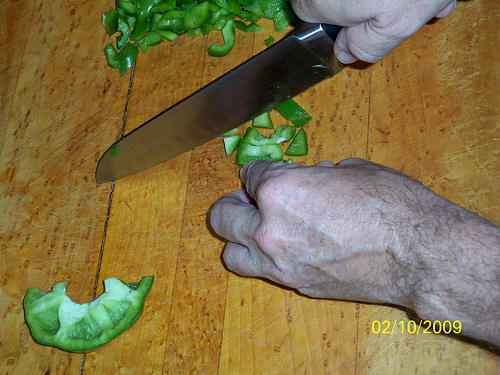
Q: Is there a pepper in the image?
A: Yes, there is a pepper.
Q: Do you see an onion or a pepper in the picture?
A: Yes, there is a pepper.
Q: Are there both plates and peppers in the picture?
A: No, there is a pepper but no plates.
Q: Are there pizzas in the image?
A: No, there are no pizzas.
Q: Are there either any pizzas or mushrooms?
A: No, there are no pizzas or mushrooms.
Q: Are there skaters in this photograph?
A: No, there are no skaters.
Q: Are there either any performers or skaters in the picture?
A: No, there are no skaters or performers.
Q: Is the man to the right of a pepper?
A: Yes, the man is to the right of a pepper.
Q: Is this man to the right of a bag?
A: No, the man is to the right of a pepper.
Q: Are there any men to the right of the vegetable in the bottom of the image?
A: Yes, there is a man to the right of the vegetable.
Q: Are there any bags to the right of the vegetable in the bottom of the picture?
A: No, there is a man to the right of the vegetable.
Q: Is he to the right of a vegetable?
A: Yes, the man is to the right of a vegetable.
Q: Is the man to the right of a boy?
A: No, the man is to the right of a vegetable.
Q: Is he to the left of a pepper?
A: No, the man is to the right of a pepper.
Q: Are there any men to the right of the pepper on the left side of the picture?
A: Yes, there is a man to the right of the pepper.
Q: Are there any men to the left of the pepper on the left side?
A: No, the man is to the right of the pepper.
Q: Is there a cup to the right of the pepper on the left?
A: No, there is a man to the right of the pepper.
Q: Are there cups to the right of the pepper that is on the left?
A: No, there is a man to the right of the pepper.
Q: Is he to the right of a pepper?
A: Yes, the man is to the right of a pepper.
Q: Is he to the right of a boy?
A: No, the man is to the right of a pepper.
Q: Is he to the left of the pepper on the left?
A: No, the man is to the right of the pepper.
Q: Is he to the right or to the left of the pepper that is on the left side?
A: The man is to the right of the pepper.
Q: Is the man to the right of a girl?
A: No, the man is to the right of a pepper.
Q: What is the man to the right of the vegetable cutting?
A: The man is cutting the pepper.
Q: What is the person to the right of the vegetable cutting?
A: The man is cutting the pepper.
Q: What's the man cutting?
A: The man is cutting the pepper.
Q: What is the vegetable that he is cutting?
A: The vegetable is a pepper.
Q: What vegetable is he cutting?
A: The man is cutting the pepper.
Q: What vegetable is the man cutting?
A: The man is cutting the pepper.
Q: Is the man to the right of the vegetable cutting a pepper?
A: Yes, the man is cutting a pepper.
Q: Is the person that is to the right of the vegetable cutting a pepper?
A: Yes, the man is cutting a pepper.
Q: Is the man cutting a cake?
A: No, the man is cutting a pepper.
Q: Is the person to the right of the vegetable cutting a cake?
A: No, the man is cutting a pepper.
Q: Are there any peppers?
A: Yes, there is a pepper.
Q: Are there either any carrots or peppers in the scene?
A: Yes, there is a pepper.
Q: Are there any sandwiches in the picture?
A: No, there are no sandwiches.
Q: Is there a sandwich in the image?
A: No, there are no sandwiches.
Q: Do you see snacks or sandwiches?
A: No, there are no sandwiches or snacks.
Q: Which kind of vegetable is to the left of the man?
A: The vegetable is a pepper.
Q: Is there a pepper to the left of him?
A: Yes, there is a pepper to the left of the man.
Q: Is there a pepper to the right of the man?
A: No, the pepper is to the left of the man.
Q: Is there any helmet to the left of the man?
A: No, there is a pepper to the left of the man.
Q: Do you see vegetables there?
A: Yes, there are vegetables.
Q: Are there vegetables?
A: Yes, there are vegetables.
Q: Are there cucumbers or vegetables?
A: Yes, there are vegetables.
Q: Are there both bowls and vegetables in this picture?
A: No, there are vegetables but no bowls.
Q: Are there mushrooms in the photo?
A: No, there are no mushrooms.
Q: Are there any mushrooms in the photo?
A: No, there are no mushrooms.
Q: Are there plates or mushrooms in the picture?
A: No, there are no mushrooms or plates.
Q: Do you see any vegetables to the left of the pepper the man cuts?
A: Yes, there are vegetables to the left of the pepper.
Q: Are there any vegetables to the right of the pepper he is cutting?
A: No, the vegetables are to the left of the pepper.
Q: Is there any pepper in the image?
A: Yes, there is a pepper.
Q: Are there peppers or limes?
A: Yes, there is a pepper.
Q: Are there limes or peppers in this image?
A: Yes, there is a pepper.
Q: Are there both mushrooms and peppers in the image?
A: No, there is a pepper but no mushrooms.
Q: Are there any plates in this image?
A: No, there are no plates.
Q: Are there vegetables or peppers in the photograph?
A: Yes, there is a pepper.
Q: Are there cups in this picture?
A: No, there are no cups.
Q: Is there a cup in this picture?
A: No, there are no cups.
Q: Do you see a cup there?
A: No, there are no cups.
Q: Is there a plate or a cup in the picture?
A: No, there are no cups or plates.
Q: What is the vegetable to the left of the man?
A: The vegetable is a pepper.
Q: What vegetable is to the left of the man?
A: The vegetable is a pepper.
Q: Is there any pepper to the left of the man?
A: Yes, there is a pepper to the left of the man.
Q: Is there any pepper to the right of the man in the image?
A: No, the pepper is to the left of the man.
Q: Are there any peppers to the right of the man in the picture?
A: No, the pepper is to the left of the man.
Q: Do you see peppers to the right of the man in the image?
A: No, the pepper is to the left of the man.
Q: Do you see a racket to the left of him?
A: No, there is a pepper to the left of the man.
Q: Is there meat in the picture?
A: No, there is no meat.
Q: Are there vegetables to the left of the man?
A: Yes, there is a vegetable to the left of the man.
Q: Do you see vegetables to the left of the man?
A: Yes, there is a vegetable to the left of the man.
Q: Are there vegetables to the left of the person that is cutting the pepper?
A: Yes, there is a vegetable to the left of the man.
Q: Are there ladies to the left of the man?
A: No, there is a vegetable to the left of the man.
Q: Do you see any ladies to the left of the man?
A: No, there is a vegetable to the left of the man.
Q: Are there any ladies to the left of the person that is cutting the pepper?
A: No, there is a vegetable to the left of the man.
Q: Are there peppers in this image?
A: Yes, there is a pepper.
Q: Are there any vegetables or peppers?
A: Yes, there is a pepper.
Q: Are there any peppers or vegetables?
A: Yes, there is a pepper.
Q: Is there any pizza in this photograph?
A: No, there are no pizzas.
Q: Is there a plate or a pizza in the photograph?
A: No, there are no pizzas or plates.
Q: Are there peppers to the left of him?
A: Yes, there is a pepper to the left of the man.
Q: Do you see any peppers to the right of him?
A: No, the pepper is to the left of the man.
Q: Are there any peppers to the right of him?
A: No, the pepper is to the left of the man.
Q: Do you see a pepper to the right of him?
A: No, the pepper is to the left of the man.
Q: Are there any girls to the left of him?
A: No, there is a pepper to the left of the man.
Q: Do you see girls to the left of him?
A: No, there is a pepper to the left of the man.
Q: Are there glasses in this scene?
A: No, there are no glasses.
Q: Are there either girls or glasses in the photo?
A: No, there are no glasses or girls.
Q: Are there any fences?
A: No, there are no fences.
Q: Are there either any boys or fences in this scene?
A: No, there are no fences or boys.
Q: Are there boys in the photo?
A: No, there are no boys.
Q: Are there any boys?
A: No, there are no boys.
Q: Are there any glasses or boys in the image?
A: No, there are no boys or glasses.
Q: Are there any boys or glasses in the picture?
A: No, there are no boys or glasses.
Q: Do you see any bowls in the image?
A: No, there are no bowls.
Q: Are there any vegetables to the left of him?
A: Yes, there is a vegetable to the left of the man.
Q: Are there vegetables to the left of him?
A: Yes, there is a vegetable to the left of the man.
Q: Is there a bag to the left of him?
A: No, there is a vegetable to the left of the man.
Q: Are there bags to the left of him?
A: No, there is a vegetable to the left of the man.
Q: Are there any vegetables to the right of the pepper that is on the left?
A: Yes, there is a vegetable to the right of the pepper.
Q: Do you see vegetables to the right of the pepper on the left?
A: Yes, there is a vegetable to the right of the pepper.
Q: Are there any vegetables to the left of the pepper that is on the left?
A: No, the vegetable is to the right of the pepper.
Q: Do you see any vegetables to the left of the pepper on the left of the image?
A: No, the vegetable is to the right of the pepper.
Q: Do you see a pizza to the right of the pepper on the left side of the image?
A: No, there is a vegetable to the right of the pepper.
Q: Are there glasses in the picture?
A: No, there are no glasses.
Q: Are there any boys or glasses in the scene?
A: No, there are no glasses or boys.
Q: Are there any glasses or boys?
A: No, there are no glasses or boys.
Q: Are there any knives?
A: Yes, there is a knife.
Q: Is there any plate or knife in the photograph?
A: Yes, there is a knife.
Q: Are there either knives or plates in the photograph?
A: Yes, there is a knife.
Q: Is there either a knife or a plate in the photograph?
A: Yes, there is a knife.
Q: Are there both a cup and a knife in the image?
A: No, there is a knife but no cups.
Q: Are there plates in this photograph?
A: No, there are no plates.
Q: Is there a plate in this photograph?
A: No, there are no plates.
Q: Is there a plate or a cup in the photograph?
A: No, there are no plates or cups.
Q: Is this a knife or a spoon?
A: This is a knife.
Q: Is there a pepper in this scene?
A: Yes, there is a pepper.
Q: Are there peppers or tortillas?
A: Yes, there is a pepper.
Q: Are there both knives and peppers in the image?
A: Yes, there are both a pepper and a knife.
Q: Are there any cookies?
A: No, there are no cookies.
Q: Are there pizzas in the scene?
A: No, there are no pizzas.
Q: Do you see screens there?
A: No, there are no screens.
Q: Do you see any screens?
A: No, there are no screens.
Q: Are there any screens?
A: No, there are no screens.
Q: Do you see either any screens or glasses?
A: No, there are no screens or glasses.